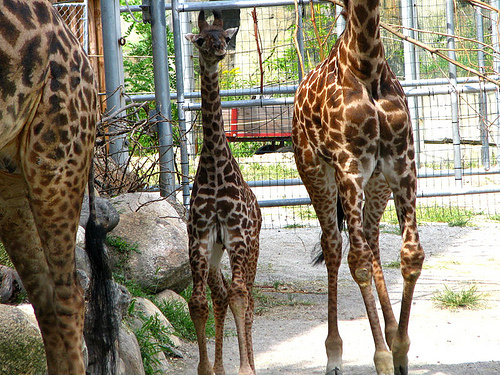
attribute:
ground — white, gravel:
[173, 220, 500, 374]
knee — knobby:
[227, 284, 250, 307]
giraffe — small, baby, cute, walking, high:
[185, 8, 263, 374]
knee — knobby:
[189, 295, 209, 319]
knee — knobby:
[211, 288, 231, 310]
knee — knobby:
[401, 245, 424, 283]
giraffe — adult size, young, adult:
[291, 1, 425, 374]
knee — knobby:
[348, 250, 376, 282]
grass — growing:
[430, 284, 487, 310]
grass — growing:
[387, 256, 403, 270]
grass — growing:
[255, 292, 313, 316]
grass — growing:
[259, 280, 289, 293]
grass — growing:
[445, 217, 469, 228]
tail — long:
[83, 158, 128, 373]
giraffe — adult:
[0, 0, 121, 374]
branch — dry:
[379, 21, 500, 138]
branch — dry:
[102, 169, 196, 192]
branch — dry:
[117, 117, 184, 193]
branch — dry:
[98, 103, 152, 129]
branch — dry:
[100, 137, 109, 195]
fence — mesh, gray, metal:
[53, 2, 499, 229]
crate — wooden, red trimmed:
[219, 104, 298, 139]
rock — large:
[1, 303, 48, 373]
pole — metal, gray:
[100, 1, 129, 169]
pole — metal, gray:
[148, 2, 177, 200]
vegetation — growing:
[148, 297, 196, 343]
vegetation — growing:
[140, 317, 178, 374]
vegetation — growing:
[107, 233, 146, 295]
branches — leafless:
[92, 81, 202, 225]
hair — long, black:
[86, 217, 122, 374]